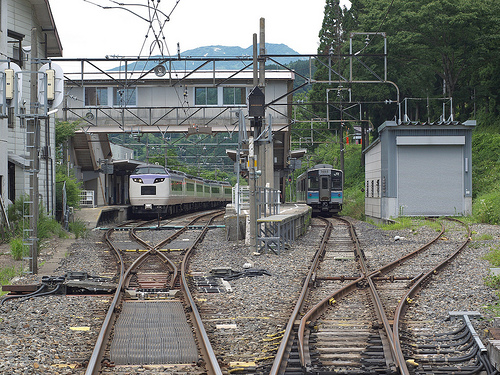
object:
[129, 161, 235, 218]
train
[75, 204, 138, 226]
platform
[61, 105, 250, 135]
bridge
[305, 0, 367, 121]
trees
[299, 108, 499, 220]
embankment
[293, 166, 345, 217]
train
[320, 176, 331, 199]
rear door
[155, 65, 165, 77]
signal light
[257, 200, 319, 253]
platform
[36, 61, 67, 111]
signal light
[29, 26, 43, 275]
pole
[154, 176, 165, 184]
light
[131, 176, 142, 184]
light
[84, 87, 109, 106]
window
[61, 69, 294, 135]
bridge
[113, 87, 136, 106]
window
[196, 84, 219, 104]
window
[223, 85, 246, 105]
window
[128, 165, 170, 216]
front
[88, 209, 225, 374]
railroad tracks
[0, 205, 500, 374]
ground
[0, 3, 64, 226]
building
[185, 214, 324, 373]
gravel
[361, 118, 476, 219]
shed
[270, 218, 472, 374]
train tracks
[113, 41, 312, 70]
mountain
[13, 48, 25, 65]
window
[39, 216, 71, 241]
grass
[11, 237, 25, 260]
grass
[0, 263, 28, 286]
grass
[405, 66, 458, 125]
antennas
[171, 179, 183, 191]
window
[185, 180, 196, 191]
window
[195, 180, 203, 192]
window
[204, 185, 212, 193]
window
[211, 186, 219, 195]
window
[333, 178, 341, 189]
window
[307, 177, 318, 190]
window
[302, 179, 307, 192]
window